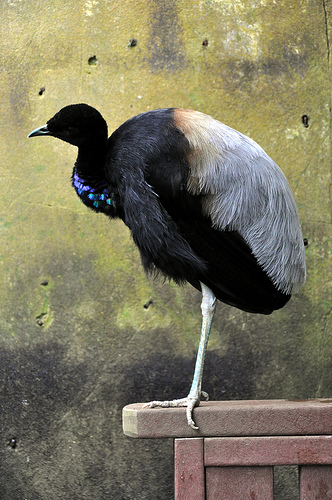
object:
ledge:
[122, 398, 332, 439]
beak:
[27, 123, 53, 140]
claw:
[189, 424, 199, 430]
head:
[28, 102, 109, 148]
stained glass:
[0, 0, 331, 499]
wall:
[2, 204, 81, 315]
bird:
[25, 102, 308, 431]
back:
[171, 107, 307, 316]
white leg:
[142, 279, 217, 429]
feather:
[119, 168, 210, 288]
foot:
[143, 383, 219, 432]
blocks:
[70, 168, 117, 221]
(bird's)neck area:
[70, 140, 116, 217]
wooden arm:
[122, 398, 332, 438]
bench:
[121, 397, 332, 500]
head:
[45, 102, 107, 149]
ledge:
[120, 397, 331, 500]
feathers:
[109, 108, 306, 315]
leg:
[142, 280, 218, 430]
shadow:
[157, 31, 265, 93]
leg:
[187, 279, 217, 402]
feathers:
[170, 108, 307, 298]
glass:
[3, 11, 315, 102]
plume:
[169, 107, 303, 298]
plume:
[216, 129, 302, 292]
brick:
[121, 400, 332, 439]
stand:
[120, 398, 332, 500]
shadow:
[111, 288, 300, 429]